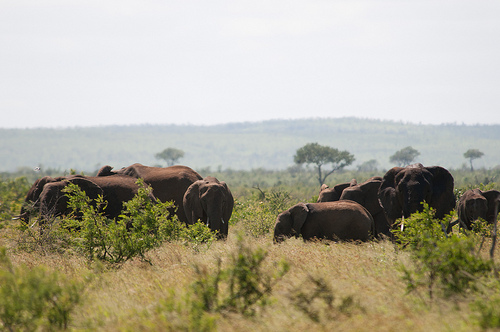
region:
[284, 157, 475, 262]
A herd of elephants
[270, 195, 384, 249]
A small baby elephant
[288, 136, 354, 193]
A tree on the savannah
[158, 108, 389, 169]
Mountainous area in the background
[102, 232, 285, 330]
Scrub brush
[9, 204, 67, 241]
Elephant tusks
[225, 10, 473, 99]
A gray cloudy sky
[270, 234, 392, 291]
Waving dry grass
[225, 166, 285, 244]
A gap between two smaller groups of elephants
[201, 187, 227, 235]
An elephant's trunk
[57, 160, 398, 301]
brown elephants eating food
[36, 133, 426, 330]
two groups of brown elephants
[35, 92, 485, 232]
very few trees around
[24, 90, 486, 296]
mountains in the background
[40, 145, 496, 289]
Eight elephants in field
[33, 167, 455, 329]
no rain for elephants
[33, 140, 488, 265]
four trees in background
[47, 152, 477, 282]
a herd of elephants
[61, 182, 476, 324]
green plants near elephants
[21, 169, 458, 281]
elephants not socializing with each other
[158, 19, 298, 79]
this is the sky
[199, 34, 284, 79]
the sky is blue in color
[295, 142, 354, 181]
this is a tree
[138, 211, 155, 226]
the tree has green leaves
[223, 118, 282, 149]
this is a mountain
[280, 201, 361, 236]
this is an elephant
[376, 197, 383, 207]
this is a tusk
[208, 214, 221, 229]
this is the trunk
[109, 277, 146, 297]
this is a grass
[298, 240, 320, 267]
the grass is dry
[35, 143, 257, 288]
four elephants grazing in Africa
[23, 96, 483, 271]
herd of African elephants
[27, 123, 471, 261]
elephants in natural habitat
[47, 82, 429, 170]
hazy trees in distance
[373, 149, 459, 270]
adult elephant with tusks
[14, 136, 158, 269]
pair of elephants facing left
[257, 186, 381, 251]
young elephant stays close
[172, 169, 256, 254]
elephant with white tusks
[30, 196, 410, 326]
elephants graze on grass and shrubs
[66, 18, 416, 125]
sky is clear but hazy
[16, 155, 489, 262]
Elephant herd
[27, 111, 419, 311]
Desert landscape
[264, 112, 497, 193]
Several trees on flat land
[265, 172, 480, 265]
Smaller elephants mixed with bigger ones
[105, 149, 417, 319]
Landscape has a lot of bushy dry vegetation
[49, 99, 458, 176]
Horizon is flat and wide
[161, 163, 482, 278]
Two elephants are facing camera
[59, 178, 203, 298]
Short trees mixed with dry brush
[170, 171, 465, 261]
A few elephants have ivory tusks in pic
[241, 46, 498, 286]
Weather is bright and sunny